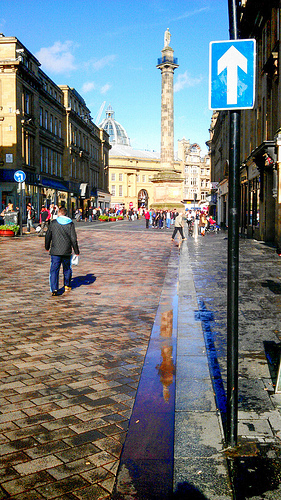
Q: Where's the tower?
A: Background.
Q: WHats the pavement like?
A: Bricks.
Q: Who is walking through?
A: Passerbys.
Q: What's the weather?
A: Slightly cloudy.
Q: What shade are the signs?
A: Blue.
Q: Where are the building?
A: All around.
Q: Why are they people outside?
A: They're walking.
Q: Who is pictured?
A: Pedestrians.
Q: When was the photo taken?
A: Daylight hours.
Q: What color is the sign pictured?
A: Blue.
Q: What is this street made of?
A: Bricks.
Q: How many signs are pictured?
A: Two.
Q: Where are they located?
A: Outside on a street.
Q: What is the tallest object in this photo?
A: A monument.